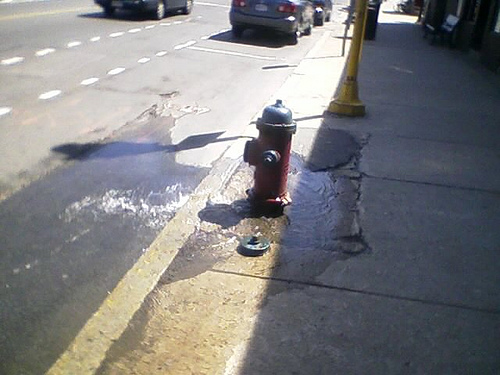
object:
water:
[0, 98, 202, 375]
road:
[1, 1, 349, 366]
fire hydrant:
[240, 100, 298, 216]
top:
[275, 99, 283, 108]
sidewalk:
[202, 14, 494, 374]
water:
[288, 129, 366, 275]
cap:
[237, 235, 271, 257]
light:
[285, 5, 293, 12]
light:
[239, 1, 246, 7]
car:
[228, 0, 314, 45]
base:
[330, 99, 367, 116]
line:
[37, 89, 62, 101]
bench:
[425, 13, 461, 47]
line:
[186, 46, 283, 62]